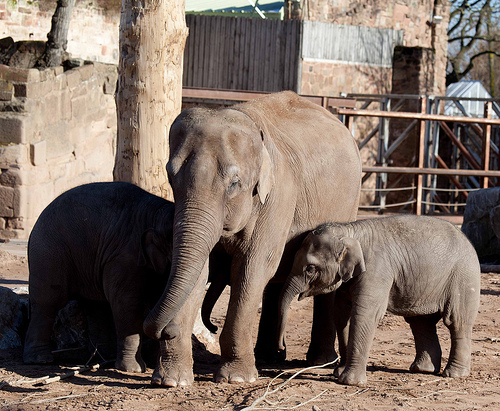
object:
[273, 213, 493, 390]
elephant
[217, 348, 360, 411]
limb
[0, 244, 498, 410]
ground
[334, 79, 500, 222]
fencing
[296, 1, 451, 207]
wall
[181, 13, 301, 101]
fence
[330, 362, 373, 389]
feet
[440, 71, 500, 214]
building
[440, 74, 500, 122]
roof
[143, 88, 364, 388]
elephant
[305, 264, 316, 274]
eye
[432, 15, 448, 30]
light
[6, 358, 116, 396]
branch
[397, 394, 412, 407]
stones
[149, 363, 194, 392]
foot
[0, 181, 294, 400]
shadow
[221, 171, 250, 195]
eyes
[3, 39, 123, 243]
wall"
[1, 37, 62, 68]
stones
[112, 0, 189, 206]
tree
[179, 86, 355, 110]
bars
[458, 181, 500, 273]
rock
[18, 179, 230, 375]
elephant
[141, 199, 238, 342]
trunk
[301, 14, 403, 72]
cover